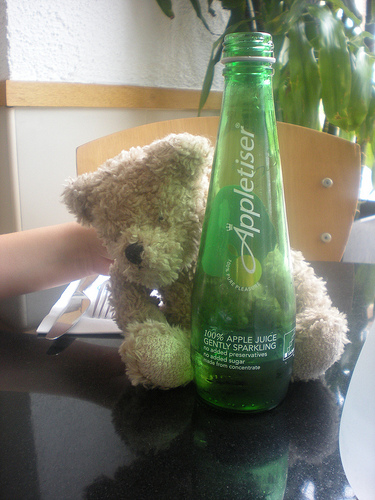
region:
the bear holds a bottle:
[162, 79, 288, 402]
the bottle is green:
[214, 173, 279, 405]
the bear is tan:
[145, 170, 205, 310]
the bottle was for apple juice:
[201, 316, 283, 372]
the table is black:
[45, 286, 349, 479]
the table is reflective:
[13, 300, 350, 489]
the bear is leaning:
[122, 141, 208, 370]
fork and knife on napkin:
[44, 254, 131, 376]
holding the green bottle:
[117, 177, 309, 369]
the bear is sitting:
[102, 190, 334, 380]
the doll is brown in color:
[110, 156, 216, 365]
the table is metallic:
[87, 405, 240, 497]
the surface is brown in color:
[70, 382, 181, 476]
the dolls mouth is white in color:
[114, 225, 174, 286]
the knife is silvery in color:
[62, 294, 90, 334]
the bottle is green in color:
[219, 151, 272, 407]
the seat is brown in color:
[293, 129, 350, 284]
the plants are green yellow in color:
[297, 26, 367, 109]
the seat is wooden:
[293, 139, 333, 270]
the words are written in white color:
[224, 114, 260, 255]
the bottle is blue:
[194, 24, 314, 433]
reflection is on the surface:
[224, 426, 291, 496]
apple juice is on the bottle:
[199, 326, 278, 365]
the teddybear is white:
[89, 145, 337, 370]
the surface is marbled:
[116, 436, 260, 490]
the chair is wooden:
[289, 126, 352, 258]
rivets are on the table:
[317, 174, 343, 244]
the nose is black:
[125, 243, 143, 267]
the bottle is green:
[179, 30, 297, 417]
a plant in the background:
[186, 13, 364, 121]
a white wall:
[11, 1, 223, 76]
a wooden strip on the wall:
[12, 80, 245, 120]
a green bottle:
[197, 44, 296, 420]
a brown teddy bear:
[69, 143, 346, 393]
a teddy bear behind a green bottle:
[80, 145, 370, 400]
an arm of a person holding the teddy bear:
[5, 219, 120, 295]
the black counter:
[5, 403, 369, 492]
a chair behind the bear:
[83, 113, 368, 266]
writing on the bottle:
[234, 132, 261, 307]